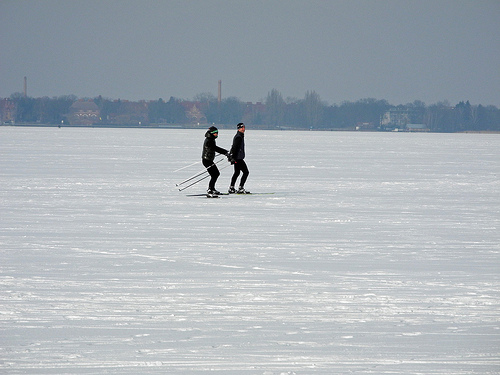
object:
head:
[205, 126, 218, 139]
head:
[237, 122, 245, 133]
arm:
[229, 137, 242, 160]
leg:
[228, 163, 241, 187]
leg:
[238, 160, 249, 189]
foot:
[228, 186, 237, 194]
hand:
[230, 158, 237, 164]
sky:
[1, 0, 500, 108]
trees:
[0, 88, 500, 134]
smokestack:
[218, 80, 222, 109]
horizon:
[0, 73, 500, 134]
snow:
[44, 219, 497, 374]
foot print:
[131, 344, 189, 358]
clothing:
[202, 131, 228, 189]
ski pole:
[174, 153, 231, 191]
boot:
[228, 186, 237, 194]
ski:
[223, 192, 275, 195]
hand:
[224, 152, 229, 157]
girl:
[201, 126, 230, 197]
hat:
[236, 123, 244, 129]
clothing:
[229, 131, 249, 188]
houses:
[0, 76, 499, 134]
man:
[229, 123, 250, 194]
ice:
[0, 125, 499, 374]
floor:
[0, 125, 499, 375]